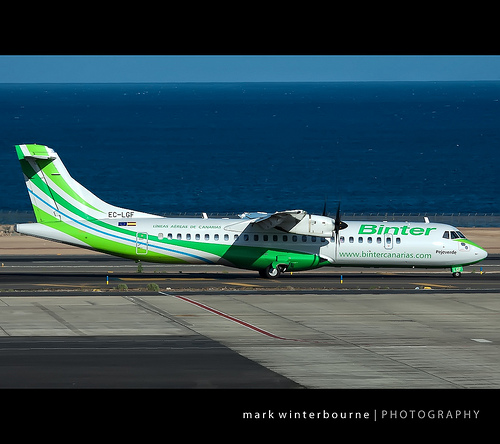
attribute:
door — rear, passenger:
[129, 228, 157, 257]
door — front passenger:
[381, 227, 397, 252]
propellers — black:
[315, 195, 345, 240]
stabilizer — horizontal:
[17, 151, 57, 165]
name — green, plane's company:
[345, 214, 441, 239]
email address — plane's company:
[313, 240, 436, 267]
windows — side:
[434, 224, 464, 239]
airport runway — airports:
[455, 226, 484, 251]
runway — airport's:
[2, 296, 482, 399]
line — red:
[163, 291, 325, 345]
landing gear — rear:
[254, 264, 288, 278]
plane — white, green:
[8, 135, 487, 287]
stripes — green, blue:
[24, 145, 321, 277]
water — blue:
[1, 81, 498, 234]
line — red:
[160, 287, 284, 338]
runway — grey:
[5, 292, 499, 386]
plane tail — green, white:
[14, 140, 159, 221]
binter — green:
[358, 220, 437, 244]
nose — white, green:
[456, 232, 487, 273]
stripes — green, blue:
[5, 131, 319, 273]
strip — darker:
[9, 258, 499, 297]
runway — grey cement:
[7, 254, 499, 383]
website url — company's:
[335, 247, 435, 264]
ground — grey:
[7, 292, 493, 388]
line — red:
[177, 290, 281, 340]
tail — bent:
[9, 135, 169, 220]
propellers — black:
[314, 197, 345, 259]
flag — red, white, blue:
[114, 218, 138, 230]